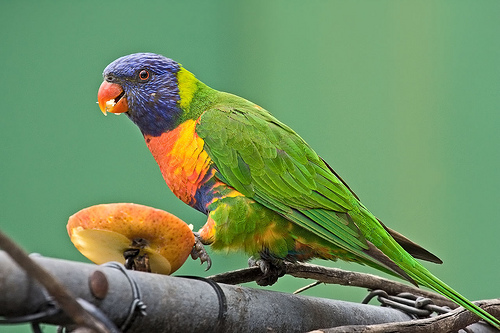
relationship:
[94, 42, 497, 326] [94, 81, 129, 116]
bird has beak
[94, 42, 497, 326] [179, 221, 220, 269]
bird has claw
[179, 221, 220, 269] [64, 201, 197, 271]
claw on potato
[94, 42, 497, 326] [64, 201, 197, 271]
bird eating potato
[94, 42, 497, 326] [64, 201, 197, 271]
bird grasping potato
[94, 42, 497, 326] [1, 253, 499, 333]
bird on branch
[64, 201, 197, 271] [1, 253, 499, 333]
potato on branch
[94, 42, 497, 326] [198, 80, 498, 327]
bird has wings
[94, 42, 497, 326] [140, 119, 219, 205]
bird has chest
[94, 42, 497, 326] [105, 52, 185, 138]
bird has face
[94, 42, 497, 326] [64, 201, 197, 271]
bird has apple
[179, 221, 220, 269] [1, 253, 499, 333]
claw holding onto branch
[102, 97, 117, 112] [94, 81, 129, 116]
food in beak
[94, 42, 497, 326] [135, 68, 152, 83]
bird has eye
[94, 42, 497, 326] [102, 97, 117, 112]
bird eating food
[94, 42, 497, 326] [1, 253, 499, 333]
bird sitting on branch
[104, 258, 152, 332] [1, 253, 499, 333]
wire on branch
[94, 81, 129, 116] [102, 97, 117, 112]
beak has food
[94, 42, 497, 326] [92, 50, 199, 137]
bird has head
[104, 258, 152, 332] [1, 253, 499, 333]
wire around branch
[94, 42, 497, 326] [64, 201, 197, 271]
bird eating apple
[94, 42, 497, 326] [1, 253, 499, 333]
bird standing on branch